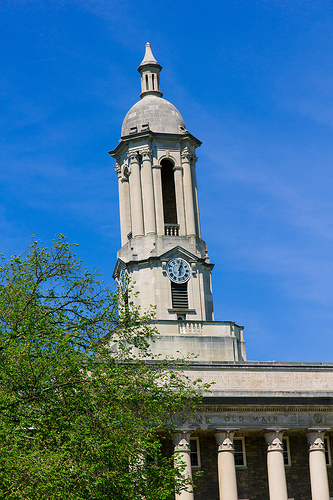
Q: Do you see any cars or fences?
A: No, there are no cars or fences.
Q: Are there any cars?
A: No, there are no cars.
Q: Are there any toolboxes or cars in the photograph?
A: No, there are no cars or toolboxes.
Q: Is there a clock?
A: Yes, there is a clock.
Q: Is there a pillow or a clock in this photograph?
A: Yes, there is a clock.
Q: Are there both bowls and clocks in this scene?
A: No, there is a clock but no bowls.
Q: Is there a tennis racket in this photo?
A: No, there are no rackets.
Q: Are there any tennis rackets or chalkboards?
A: No, there are no tennis rackets or chalkboards.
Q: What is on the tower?
A: The clock is on the tower.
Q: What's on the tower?
A: The clock is on the tower.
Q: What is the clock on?
A: The clock is on the tower.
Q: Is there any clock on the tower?
A: Yes, there is a clock on the tower.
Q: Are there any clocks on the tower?
A: Yes, there is a clock on the tower.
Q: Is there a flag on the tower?
A: No, there is a clock on the tower.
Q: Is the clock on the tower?
A: Yes, the clock is on the tower.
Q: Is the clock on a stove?
A: No, the clock is on the tower.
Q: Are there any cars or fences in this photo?
A: No, there are no cars or fences.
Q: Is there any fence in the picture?
A: No, there are no fences.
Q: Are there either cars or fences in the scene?
A: No, there are no fences or cars.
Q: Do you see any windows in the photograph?
A: Yes, there are windows.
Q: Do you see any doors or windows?
A: Yes, there are windows.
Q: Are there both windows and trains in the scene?
A: No, there are windows but no trains.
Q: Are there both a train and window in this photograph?
A: No, there are windows but no trains.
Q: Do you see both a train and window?
A: No, there are windows but no trains.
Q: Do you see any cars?
A: No, there are no cars.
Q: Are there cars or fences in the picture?
A: No, there are no cars or fences.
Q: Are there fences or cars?
A: No, there are no cars or fences.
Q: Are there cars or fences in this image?
A: No, there are no cars or fences.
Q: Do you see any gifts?
A: No, there are no gifts.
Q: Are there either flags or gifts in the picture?
A: No, there are no gifts or flags.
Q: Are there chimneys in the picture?
A: No, there are no chimneys.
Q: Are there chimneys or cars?
A: No, there are no chimneys or cars.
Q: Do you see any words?
A: Yes, there are words.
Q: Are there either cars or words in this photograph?
A: Yes, there are words.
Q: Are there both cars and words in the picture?
A: No, there are words but no cars.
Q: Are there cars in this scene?
A: No, there are no cars.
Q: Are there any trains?
A: No, there are no trains.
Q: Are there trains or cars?
A: No, there are no trains or cars.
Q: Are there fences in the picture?
A: No, there are no fences.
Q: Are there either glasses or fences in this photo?
A: No, there are no fences or glasses.